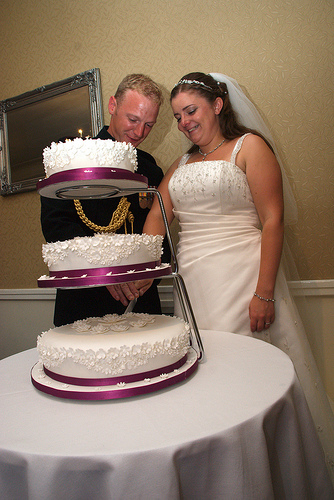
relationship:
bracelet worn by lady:
[247, 284, 287, 307] [130, 69, 285, 500]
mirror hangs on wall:
[0, 66, 113, 195] [0, 0, 332, 82]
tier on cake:
[37, 135, 147, 201] [38, 143, 212, 393]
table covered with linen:
[166, 398, 212, 428] [0, 325, 331, 498]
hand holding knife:
[132, 277, 155, 295] [121, 293, 139, 313]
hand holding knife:
[247, 286, 281, 334] [121, 292, 141, 315]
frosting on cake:
[41, 135, 139, 176] [35, 136, 191, 380]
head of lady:
[170, 72, 233, 155] [164, 69, 237, 144]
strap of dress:
[224, 131, 257, 166] [174, 131, 329, 495]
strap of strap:
[177, 145, 189, 168] [224, 131, 257, 166]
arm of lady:
[201, 130, 285, 332] [94, 68, 312, 474]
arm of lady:
[117, 142, 184, 297] [94, 68, 312, 474]